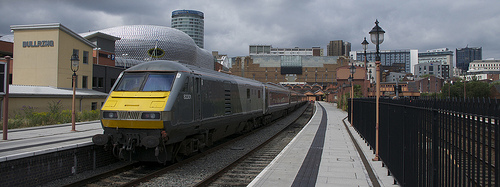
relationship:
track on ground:
[90, 100, 313, 170] [249, 65, 396, 185]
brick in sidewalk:
[327, 114, 357, 178] [318, 95, 363, 182]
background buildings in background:
[225, 40, 499, 104] [165, 3, 496, 90]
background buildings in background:
[247, 42, 497, 119] [165, 3, 496, 90]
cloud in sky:
[0, 0, 498, 48] [0, 0, 499, 59]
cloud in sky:
[0, 0, 498, 48] [402, 0, 468, 38]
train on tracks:
[90, 48, 300, 140] [19, 157, 280, 185]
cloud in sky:
[0, 0, 498, 48] [223, 11, 355, 51]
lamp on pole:
[368, 19, 385, 45] [373, 43, 380, 160]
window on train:
[111, 70, 183, 93] [91, 49, 301, 154]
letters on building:
[10, 38, 54, 48] [5, 22, 85, 85]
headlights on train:
[89, 103, 209, 143] [131, 61, 331, 136]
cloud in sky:
[0, 0, 498, 48] [389, 7, 499, 44]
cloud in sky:
[344, 7, 497, 73] [3, 5, 484, 85]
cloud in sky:
[0, 0, 498, 48] [222, 6, 256, 38]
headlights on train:
[100, 108, 162, 121] [83, 44, 314, 145]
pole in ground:
[363, 18, 393, 168] [221, 90, 375, 185]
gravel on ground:
[149, 127, 273, 182] [250, 90, 387, 185]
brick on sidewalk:
[330, 161, 357, 178] [297, 96, 372, 185]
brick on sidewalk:
[327, 114, 357, 178] [309, 92, 346, 185]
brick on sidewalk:
[327, 114, 357, 178] [316, 92, 376, 184]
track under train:
[38, 68, 348, 170] [81, 45, 321, 159]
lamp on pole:
[363, 19, 384, 46] [373, 43, 380, 160]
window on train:
[118, 62, 208, 109] [92, 63, 357, 156]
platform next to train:
[1, 117, 131, 159] [93, 55, 308, 168]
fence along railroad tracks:
[340, 88, 493, 178] [69, 93, 321, 182]